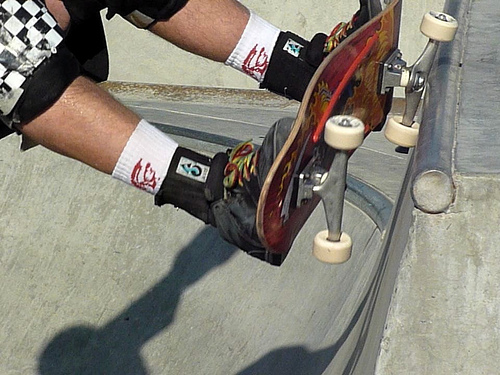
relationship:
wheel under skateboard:
[325, 115, 365, 150] [259, 1, 458, 253]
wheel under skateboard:
[309, 227, 357, 270] [259, 1, 458, 253]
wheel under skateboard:
[378, 109, 426, 152] [259, 1, 458, 253]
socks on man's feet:
[110, 117, 172, 204] [155, 2, 380, 274]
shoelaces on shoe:
[217, 119, 256, 211] [199, 115, 303, 264]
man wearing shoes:
[2, 0, 385, 263] [220, 2, 402, 277]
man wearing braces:
[2, 0, 385, 263] [165, 147, 222, 214]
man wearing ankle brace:
[2, 0, 385, 263] [152, 146, 225, 228]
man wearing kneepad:
[2, 0, 385, 263] [0, 0, 92, 109]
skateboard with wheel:
[259, 1, 458, 253] [325, 115, 365, 150]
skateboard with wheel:
[259, 1, 458, 253] [315, 228, 351, 261]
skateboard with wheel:
[259, 1, 458, 253] [418, 9, 459, 43]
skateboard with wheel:
[259, 1, 458, 253] [381, 112, 421, 145]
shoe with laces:
[210, 116, 298, 271] [319, 21, 348, 53]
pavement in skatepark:
[22, 182, 425, 363] [0, 0, 498, 370]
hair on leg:
[182, 9, 207, 23] [1, 35, 213, 225]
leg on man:
[111, 2, 308, 88] [2, 0, 385, 263]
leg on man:
[1, 35, 213, 225] [2, 0, 385, 263]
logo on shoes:
[173, 155, 210, 181] [152, 0, 391, 264]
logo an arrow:
[173, 155, 210, 181] [172, 157, 220, 179]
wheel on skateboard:
[415, 3, 465, 48] [259, 0, 405, 259]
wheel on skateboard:
[378, 109, 426, 152] [259, 0, 405, 259]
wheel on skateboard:
[317, 108, 373, 155] [259, 0, 405, 259]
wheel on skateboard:
[309, 227, 357, 270] [259, 0, 405, 259]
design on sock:
[128, 155, 157, 190] [99, 117, 176, 199]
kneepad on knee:
[0, 2, 83, 134] [4, 4, 100, 111]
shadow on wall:
[36, 214, 370, 373] [362, 48, 492, 368]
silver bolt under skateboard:
[295, 152, 328, 208] [259, 1, 458, 253]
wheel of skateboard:
[325, 115, 365, 150] [259, 1, 458, 253]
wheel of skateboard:
[309, 227, 357, 270] [259, 1, 458, 253]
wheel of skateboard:
[378, 109, 426, 152] [259, 1, 458, 253]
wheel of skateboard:
[415, 3, 465, 48] [259, 1, 458, 253]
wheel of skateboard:
[309, 227, 357, 270] [255, 22, 408, 264]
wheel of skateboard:
[325, 115, 365, 150] [255, 22, 408, 264]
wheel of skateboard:
[378, 109, 426, 152] [255, 22, 408, 264]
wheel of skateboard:
[415, 3, 465, 48] [255, 22, 408, 264]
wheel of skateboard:
[312, 229, 352, 261] [259, 1, 458, 253]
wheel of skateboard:
[383, 114, 421, 147] [259, 1, 458, 253]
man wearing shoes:
[2, 0, 385, 263] [150, 111, 331, 271]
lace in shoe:
[213, 135, 269, 208] [206, 116, 296, 271]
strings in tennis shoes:
[311, 16, 354, 53] [157, 115, 300, 267]